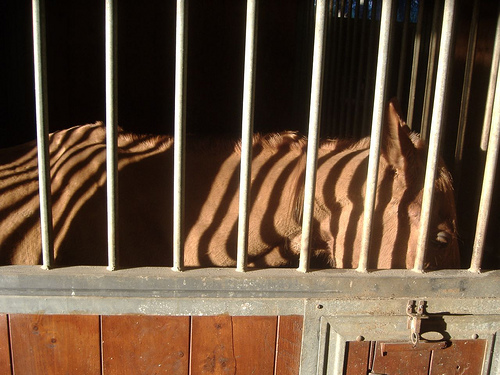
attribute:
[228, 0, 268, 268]
bar — metal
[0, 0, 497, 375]
stall — one, horse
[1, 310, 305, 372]
wall — wooden, one, stable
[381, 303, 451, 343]
latch — one, small 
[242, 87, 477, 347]
door — one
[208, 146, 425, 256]
shadow — lined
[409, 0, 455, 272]
bar — metal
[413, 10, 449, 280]
bar — metal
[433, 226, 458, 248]
eye — one, equine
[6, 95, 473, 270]
horse — one, brown 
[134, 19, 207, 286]
bar — metal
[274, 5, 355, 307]
bar — metal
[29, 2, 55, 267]
bar — metal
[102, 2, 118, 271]
bar — metal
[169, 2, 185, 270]
bar — metal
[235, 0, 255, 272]
bar — metal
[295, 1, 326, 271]
bar — metal